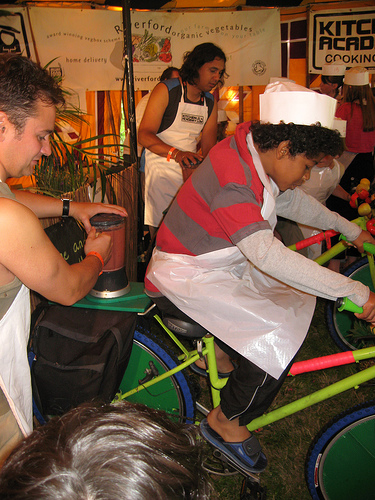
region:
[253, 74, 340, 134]
white hat on the head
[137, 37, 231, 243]
man wearing a white apron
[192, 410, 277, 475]
black and blue sandal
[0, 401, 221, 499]
top of someone's head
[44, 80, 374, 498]
little kid on a stationary bike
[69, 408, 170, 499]
light shining on the hair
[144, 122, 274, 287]
red and gray striped shirt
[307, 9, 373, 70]
black and white sign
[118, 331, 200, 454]
green and blue wheel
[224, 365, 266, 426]
white stripe on the side of the black pants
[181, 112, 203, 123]
logo on the apron.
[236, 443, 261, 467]
sandal on man's foot.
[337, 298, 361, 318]
handlebar on the bike.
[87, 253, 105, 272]
bracelet on man's wrist.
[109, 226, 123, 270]
blender on the table.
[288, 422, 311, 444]
grass on the ground.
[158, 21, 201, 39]
writing on the banner.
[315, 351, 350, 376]
pink tape on bicycle.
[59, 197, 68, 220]
watch on man's wrist.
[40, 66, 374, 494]
boy on a bike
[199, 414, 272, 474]
blue and black sandal on the foot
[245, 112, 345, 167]
hair sticking out from under the hat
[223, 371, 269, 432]
thin white stripe on the side of the pant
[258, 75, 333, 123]
boy wearing a white cooking hat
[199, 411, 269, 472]
boy wearing a blue sandal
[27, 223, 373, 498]
an indoor colorful bike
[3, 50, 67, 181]
man with short brown hair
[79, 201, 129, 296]
man preparing a smoothie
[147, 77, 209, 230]
man wearing a white apron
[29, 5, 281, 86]
a white banner suspended from the ceiling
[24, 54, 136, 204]
green leaf of an indoor palm tree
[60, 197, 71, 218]
man wearing a black watch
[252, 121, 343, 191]
boy with curly brown hair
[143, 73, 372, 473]
A man on a bicycle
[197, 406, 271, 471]
A blue sandal on the man's feet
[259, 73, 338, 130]
A white hat on the man's head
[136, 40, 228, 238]
A man standing in the background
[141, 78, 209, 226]
A white apron on the man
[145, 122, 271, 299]
A red and gray striped shirt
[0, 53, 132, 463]
A man holding a container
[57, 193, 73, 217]
A black watch on the man's wrist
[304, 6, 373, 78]
A white sign with black letters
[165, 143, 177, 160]
An orange bracelet on the man's wrist